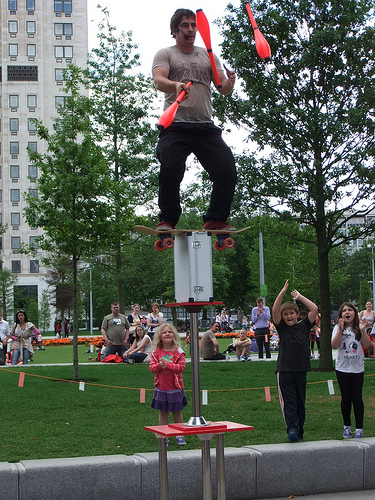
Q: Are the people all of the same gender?
A: No, they are both male and female.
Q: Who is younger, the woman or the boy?
A: The boy is younger than the woman.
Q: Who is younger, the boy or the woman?
A: The boy is younger than the woman.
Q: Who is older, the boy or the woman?
A: The woman is older than the boy.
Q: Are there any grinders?
A: No, there are no grinders.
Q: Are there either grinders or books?
A: No, there are no grinders or books.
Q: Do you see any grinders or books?
A: No, there are no grinders or books.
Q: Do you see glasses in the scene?
A: No, there are no glasses.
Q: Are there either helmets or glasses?
A: No, there are no glasses or helmets.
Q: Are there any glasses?
A: No, there are no glasses.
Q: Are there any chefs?
A: No, there are no chefs.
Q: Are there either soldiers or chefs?
A: No, there are no chefs or soldiers.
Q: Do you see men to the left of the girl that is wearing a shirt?
A: Yes, there is a man to the left of the girl.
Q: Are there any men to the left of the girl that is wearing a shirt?
A: Yes, there is a man to the left of the girl.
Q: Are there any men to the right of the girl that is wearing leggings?
A: No, the man is to the left of the girl.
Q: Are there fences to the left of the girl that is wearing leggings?
A: No, there is a man to the left of the girl.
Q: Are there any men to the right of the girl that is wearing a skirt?
A: Yes, there is a man to the right of the girl.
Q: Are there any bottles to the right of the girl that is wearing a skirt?
A: No, there is a man to the right of the girl.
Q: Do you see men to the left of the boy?
A: Yes, there is a man to the left of the boy.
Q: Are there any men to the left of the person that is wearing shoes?
A: Yes, there is a man to the left of the boy.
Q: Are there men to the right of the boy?
A: No, the man is to the left of the boy.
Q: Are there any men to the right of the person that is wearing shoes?
A: No, the man is to the left of the boy.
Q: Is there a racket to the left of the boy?
A: No, there is a man to the left of the boy.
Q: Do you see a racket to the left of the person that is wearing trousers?
A: No, there is a man to the left of the boy.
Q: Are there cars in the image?
A: No, there are no cars.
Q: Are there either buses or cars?
A: No, there are no cars or buses.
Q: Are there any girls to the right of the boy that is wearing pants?
A: Yes, there is a girl to the right of the boy.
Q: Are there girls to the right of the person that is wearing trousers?
A: Yes, there is a girl to the right of the boy.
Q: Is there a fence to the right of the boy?
A: No, there is a girl to the right of the boy.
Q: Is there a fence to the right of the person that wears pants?
A: No, there is a girl to the right of the boy.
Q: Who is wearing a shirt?
A: The girl is wearing a shirt.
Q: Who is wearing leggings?
A: The girl is wearing leggings.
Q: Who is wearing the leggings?
A: The girl is wearing leggings.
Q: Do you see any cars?
A: No, there are no cars.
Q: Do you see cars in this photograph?
A: No, there are no cars.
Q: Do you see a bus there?
A: No, there are no buses.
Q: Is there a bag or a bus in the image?
A: No, there are no buses or bags.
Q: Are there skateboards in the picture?
A: Yes, there is a skateboard.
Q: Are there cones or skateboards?
A: Yes, there is a skateboard.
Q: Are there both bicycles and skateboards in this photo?
A: No, there is a skateboard but no bicycles.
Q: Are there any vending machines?
A: No, there are no vending machines.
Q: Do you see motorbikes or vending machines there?
A: No, there are no vending machines or motorbikes.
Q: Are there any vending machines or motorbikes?
A: No, there are no vending machines or motorbikes.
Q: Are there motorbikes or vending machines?
A: No, there are no vending machines or motorbikes.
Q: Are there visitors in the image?
A: No, there are no visitors.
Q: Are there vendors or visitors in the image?
A: No, there are no visitors or vendors.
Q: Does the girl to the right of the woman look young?
A: Yes, the girl is young.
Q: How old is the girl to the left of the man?
A: The girl is young.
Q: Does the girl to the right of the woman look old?
A: No, the girl is young.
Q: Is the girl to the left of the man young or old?
A: The girl is young.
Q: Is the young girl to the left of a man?
A: No, the girl is to the right of a man.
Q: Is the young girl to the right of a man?
A: No, the girl is to the left of a man.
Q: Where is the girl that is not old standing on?
A: The girl is standing on the grass.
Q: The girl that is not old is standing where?
A: The girl is standing on the grass.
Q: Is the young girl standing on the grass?
A: Yes, the girl is standing on the grass.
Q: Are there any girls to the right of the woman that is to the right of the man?
A: Yes, there is a girl to the right of the woman.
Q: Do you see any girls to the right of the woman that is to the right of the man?
A: Yes, there is a girl to the right of the woman.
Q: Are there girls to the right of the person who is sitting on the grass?
A: Yes, there is a girl to the right of the woman.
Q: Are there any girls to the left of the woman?
A: No, the girl is to the right of the woman.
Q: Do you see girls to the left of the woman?
A: No, the girl is to the right of the woman.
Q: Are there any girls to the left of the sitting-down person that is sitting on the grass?
A: No, the girl is to the right of the woman.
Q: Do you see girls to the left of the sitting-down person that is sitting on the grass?
A: No, the girl is to the right of the woman.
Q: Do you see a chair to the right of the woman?
A: No, there is a girl to the right of the woman.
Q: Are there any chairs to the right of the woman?
A: No, there is a girl to the right of the woman.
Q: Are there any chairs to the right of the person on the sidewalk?
A: No, there is a girl to the right of the woman.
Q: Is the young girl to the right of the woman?
A: Yes, the girl is to the right of the woman.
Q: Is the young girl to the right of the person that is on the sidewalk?
A: Yes, the girl is to the right of the woman.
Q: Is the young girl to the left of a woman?
A: No, the girl is to the right of a woman.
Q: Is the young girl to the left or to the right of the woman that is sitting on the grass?
A: The girl is to the right of the woman.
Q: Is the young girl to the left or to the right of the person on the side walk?
A: The girl is to the right of the woman.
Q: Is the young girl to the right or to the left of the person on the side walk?
A: The girl is to the right of the woman.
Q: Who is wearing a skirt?
A: The girl is wearing a skirt.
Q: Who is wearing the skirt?
A: The girl is wearing a skirt.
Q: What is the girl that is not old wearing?
A: The girl is wearing a skirt.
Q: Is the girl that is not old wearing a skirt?
A: Yes, the girl is wearing a skirt.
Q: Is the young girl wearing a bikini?
A: No, the girl is wearing a skirt.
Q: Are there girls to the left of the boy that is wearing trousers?
A: Yes, there is a girl to the left of the boy.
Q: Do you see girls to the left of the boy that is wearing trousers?
A: Yes, there is a girl to the left of the boy.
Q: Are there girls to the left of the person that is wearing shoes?
A: Yes, there is a girl to the left of the boy.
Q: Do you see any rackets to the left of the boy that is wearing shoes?
A: No, there is a girl to the left of the boy.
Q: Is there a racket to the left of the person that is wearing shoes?
A: No, there is a girl to the left of the boy.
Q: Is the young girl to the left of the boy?
A: Yes, the girl is to the left of the boy.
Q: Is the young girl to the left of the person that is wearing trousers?
A: Yes, the girl is to the left of the boy.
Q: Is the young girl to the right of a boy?
A: No, the girl is to the left of a boy.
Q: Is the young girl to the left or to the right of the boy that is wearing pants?
A: The girl is to the left of the boy.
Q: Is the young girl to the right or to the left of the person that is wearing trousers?
A: The girl is to the left of the boy.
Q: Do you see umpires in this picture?
A: No, there are no umpires.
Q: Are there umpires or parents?
A: No, there are no umpires or parents.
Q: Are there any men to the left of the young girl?
A: Yes, there is a man to the left of the girl.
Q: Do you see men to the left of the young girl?
A: Yes, there is a man to the left of the girl.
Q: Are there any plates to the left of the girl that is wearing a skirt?
A: No, there is a man to the left of the girl.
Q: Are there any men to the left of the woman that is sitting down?
A: Yes, there is a man to the left of the woman.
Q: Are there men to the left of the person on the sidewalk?
A: Yes, there is a man to the left of the woman.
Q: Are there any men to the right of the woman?
A: No, the man is to the left of the woman.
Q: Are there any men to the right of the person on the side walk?
A: No, the man is to the left of the woman.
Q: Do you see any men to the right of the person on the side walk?
A: No, the man is to the left of the woman.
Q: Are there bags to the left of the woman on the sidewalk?
A: No, there is a man to the left of the woman.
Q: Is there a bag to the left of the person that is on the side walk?
A: No, there is a man to the left of the woman.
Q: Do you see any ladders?
A: No, there are no ladders.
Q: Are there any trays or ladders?
A: No, there are no ladders or trays.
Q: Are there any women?
A: Yes, there is a woman.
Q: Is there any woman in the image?
A: Yes, there is a woman.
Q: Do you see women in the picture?
A: Yes, there is a woman.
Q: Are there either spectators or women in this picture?
A: Yes, there is a woman.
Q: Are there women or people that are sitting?
A: Yes, the woman is sitting.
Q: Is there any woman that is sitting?
A: Yes, there is a woman that is sitting.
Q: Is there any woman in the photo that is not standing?
A: Yes, there is a woman that is sitting.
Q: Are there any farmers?
A: No, there are no farmers.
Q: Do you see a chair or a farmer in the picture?
A: No, there are no farmers or chairs.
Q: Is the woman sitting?
A: Yes, the woman is sitting.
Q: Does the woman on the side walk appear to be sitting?
A: Yes, the woman is sitting.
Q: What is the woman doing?
A: The woman is sitting.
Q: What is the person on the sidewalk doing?
A: The woman is sitting.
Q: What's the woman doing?
A: The woman is sitting.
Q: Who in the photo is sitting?
A: The woman is sitting.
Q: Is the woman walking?
A: No, the woman is sitting.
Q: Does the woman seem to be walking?
A: No, the woman is sitting.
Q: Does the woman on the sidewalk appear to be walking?
A: No, the woman is sitting.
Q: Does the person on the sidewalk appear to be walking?
A: No, the woman is sitting.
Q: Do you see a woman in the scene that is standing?
A: No, there is a woman but she is sitting.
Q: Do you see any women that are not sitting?
A: No, there is a woman but she is sitting.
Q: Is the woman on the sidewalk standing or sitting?
A: The woman is sitting.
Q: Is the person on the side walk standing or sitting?
A: The woman is sitting.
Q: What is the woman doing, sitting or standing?
A: The woman is sitting.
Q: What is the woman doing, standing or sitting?
A: The woman is sitting.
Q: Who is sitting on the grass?
A: The woman is sitting on the grass.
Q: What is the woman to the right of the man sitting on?
A: The woman is sitting on the grass.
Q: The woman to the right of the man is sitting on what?
A: The woman is sitting on the grass.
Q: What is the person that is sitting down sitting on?
A: The woman is sitting on the grass.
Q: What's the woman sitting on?
A: The woman is sitting on the grass.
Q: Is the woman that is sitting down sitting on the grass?
A: Yes, the woman is sitting on the grass.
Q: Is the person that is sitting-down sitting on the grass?
A: Yes, the woman is sitting on the grass.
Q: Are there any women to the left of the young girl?
A: Yes, there is a woman to the left of the girl.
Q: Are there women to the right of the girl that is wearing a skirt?
A: No, the woman is to the left of the girl.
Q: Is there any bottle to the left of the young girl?
A: No, there is a woman to the left of the girl.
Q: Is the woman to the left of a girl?
A: Yes, the woman is to the left of a girl.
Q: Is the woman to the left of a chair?
A: No, the woman is to the left of a girl.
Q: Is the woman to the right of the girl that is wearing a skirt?
A: No, the woman is to the left of the girl.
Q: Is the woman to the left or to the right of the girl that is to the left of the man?
A: The woman is to the left of the girl.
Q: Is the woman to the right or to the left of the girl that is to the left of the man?
A: The woman is to the left of the girl.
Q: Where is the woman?
A: The woman is on the sidewalk.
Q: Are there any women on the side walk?
A: Yes, there is a woman on the side walk.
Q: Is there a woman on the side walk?
A: Yes, there is a woman on the side walk.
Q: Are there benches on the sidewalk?
A: No, there is a woman on the sidewalk.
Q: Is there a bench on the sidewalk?
A: No, there is a woman on the sidewalk.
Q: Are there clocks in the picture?
A: No, there are no clocks.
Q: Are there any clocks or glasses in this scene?
A: No, there are no clocks or glasses.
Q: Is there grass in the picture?
A: Yes, there is grass.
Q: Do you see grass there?
A: Yes, there is grass.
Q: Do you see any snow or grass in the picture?
A: Yes, there is grass.